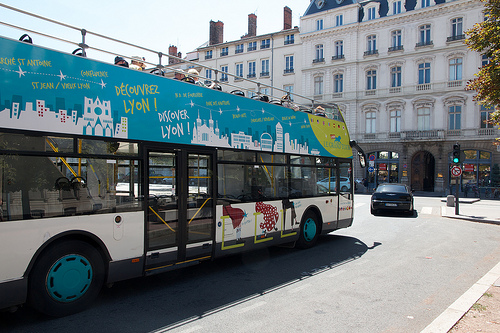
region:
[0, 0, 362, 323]
white and green double-decker bus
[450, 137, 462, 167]
traffic light shining green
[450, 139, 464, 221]
traffic light pole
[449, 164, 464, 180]
red white and black sign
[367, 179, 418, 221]
dark gray car driving through intersection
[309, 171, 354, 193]
white car parked along street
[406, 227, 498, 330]
sidewalk near bus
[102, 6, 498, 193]
large white building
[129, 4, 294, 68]
several chimneys on top of large white building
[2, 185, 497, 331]
gray concrete city street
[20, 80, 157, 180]
the print is white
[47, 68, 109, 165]
the print is white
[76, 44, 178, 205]
the print is white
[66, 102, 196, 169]
the print is white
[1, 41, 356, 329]
Blue, white and black bus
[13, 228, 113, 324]
Rear right wheel of bus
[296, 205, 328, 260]
Right front wheel of bus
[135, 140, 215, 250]
Back exit passenger door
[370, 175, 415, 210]
Back of black car in front of bus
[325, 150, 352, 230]
Front entrance/exit passenger door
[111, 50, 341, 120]
People sitting on top level of bus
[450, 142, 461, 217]
Black traffic sign with green light on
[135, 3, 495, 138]
Tall white building with lots of windows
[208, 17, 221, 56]
Chimney on top of large white building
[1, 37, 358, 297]
a blue, white, and yellow bus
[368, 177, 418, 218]
a black car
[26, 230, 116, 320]
a black wheel on a bus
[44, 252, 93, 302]
a blue hubcap on a bus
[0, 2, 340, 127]
an upper, open deck level on a bus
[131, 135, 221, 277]
double doors on a bus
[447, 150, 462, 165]
a green light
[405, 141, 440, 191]
an arched doorway in a building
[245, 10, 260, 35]
a brick chimney on a building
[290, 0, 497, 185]
a large white building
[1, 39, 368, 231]
bus is white and blue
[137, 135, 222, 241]
two doors in middle of bus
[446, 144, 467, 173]
traffic light is green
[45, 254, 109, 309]
blue hubcap on wheels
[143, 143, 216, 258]
black frame on bus doors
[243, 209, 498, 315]
grey city street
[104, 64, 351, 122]
people sitting on top of bus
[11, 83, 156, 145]
cityscape drawn on bus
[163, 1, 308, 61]
numerous chimneys on building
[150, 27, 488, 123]
many windows on building